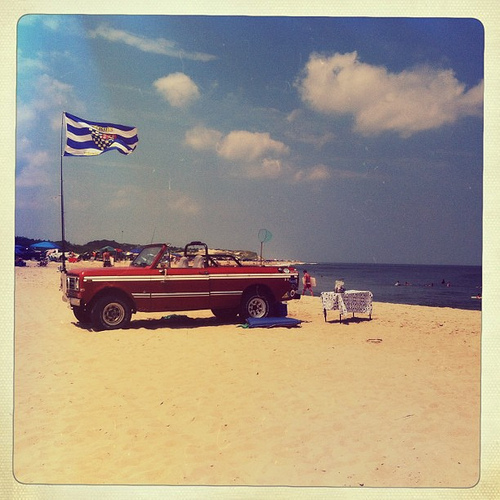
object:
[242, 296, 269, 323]
tire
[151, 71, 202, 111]
clouds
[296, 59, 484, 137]
clouds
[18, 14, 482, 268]
sky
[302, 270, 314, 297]
man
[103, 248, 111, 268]
man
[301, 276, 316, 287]
board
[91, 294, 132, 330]
tire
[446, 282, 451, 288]
people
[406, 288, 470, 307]
water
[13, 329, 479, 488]
sand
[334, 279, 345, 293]
bag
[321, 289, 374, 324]
table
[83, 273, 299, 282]
lines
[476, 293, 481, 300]
people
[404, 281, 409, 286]
people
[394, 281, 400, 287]
people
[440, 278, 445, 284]
people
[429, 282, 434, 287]
people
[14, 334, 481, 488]
beach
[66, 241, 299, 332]
truck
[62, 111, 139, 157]
flag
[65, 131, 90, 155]
stripe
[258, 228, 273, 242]
net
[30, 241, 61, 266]
umbrella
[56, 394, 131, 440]
footprints